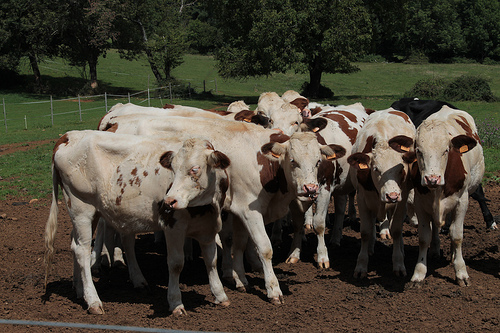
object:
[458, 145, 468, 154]
tag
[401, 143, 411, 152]
tag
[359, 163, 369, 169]
tag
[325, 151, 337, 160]
tag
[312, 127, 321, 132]
tag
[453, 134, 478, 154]
ear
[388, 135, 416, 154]
ear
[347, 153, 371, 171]
ear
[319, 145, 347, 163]
ear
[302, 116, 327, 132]
ear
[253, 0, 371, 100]
tree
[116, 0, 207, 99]
tree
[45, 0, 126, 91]
tree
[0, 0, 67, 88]
tree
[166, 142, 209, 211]
cow face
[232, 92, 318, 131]
calve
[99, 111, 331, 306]
calve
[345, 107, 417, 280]
calve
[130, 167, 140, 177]
spot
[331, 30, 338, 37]
green leaf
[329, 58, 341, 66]
green leaf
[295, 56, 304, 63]
green leaf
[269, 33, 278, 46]
green leaf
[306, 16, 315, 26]
green leaf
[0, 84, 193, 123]
fence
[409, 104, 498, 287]
calve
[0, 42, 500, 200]
grass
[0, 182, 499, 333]
dirt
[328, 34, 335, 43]
leaf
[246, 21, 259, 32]
leaf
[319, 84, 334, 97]
bush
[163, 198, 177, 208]
nose